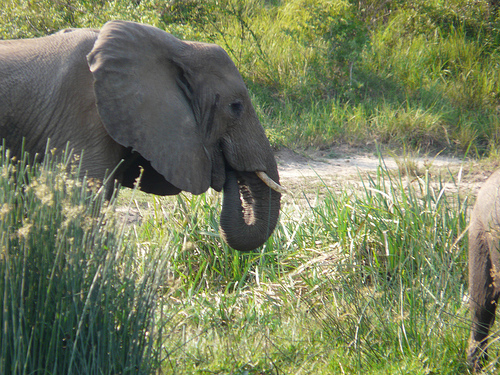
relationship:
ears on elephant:
[90, 33, 195, 200] [26, 41, 321, 246]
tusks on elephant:
[254, 168, 289, 204] [26, 41, 321, 246]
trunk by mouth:
[223, 189, 291, 255] [215, 160, 251, 192]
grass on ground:
[53, 224, 423, 374] [30, 254, 464, 374]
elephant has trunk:
[26, 41, 321, 246] [223, 189, 291, 255]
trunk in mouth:
[223, 189, 291, 255] [215, 160, 251, 192]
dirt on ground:
[294, 170, 372, 219] [30, 254, 464, 374]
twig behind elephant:
[291, 146, 355, 172] [26, 41, 321, 246]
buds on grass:
[49, 211, 107, 261] [53, 224, 423, 374]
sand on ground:
[275, 147, 393, 169] [30, 254, 464, 374]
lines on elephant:
[35, 82, 69, 168] [26, 41, 321, 246]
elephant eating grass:
[26, 41, 321, 246] [53, 224, 423, 374]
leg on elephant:
[456, 256, 500, 369] [416, 154, 493, 350]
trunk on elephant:
[223, 189, 291, 255] [26, 41, 321, 246]